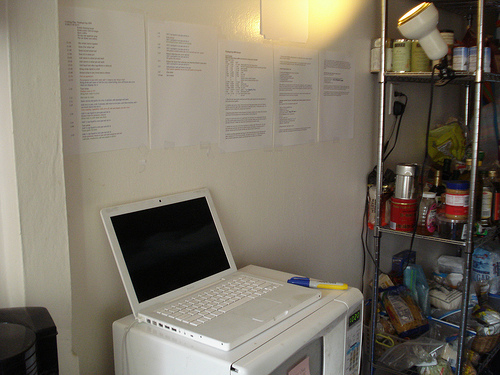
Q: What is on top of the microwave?
A: Laptop.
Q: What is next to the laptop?
A: Marker.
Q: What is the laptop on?
A: Microwave.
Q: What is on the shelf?
A: Pantry items.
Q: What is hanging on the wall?
A: Printed sheets.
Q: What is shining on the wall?
A: Light.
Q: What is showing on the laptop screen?
A: Nothing.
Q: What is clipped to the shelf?
A: Light.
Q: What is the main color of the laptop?
A: White.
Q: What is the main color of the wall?
A: White.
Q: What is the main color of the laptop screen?
A: Black.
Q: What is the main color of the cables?
A: Black.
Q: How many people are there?
A: None.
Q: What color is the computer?
A: White.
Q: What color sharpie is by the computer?
A: Blue.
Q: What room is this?
A: Kitchen.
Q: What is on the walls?
A: Recipes.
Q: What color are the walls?
A: Cream.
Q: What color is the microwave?
A: Pure white.